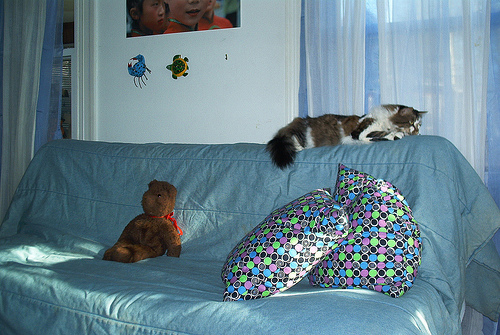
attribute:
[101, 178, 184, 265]
teddy bear — brown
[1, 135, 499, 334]
couch — blue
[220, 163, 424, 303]
pillows — colorful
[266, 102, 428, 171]
cat — black, gray, white, long-haired, large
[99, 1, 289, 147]
wall — white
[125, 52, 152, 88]
crab — blue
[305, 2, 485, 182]
curtains — sheer, white, blue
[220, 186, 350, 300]
pillow — falling down, colorful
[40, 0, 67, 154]
curtain — blue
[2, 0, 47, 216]
curtain — white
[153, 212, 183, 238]
ribbon — red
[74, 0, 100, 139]
window trim — white